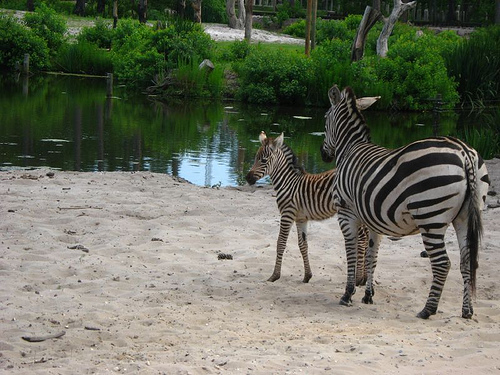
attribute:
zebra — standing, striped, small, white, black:
[319, 82, 490, 322]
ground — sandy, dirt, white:
[3, 173, 499, 373]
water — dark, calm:
[4, 67, 499, 186]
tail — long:
[463, 152, 483, 298]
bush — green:
[111, 16, 179, 89]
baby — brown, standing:
[241, 125, 380, 290]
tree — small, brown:
[215, 2, 257, 30]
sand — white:
[206, 23, 251, 44]